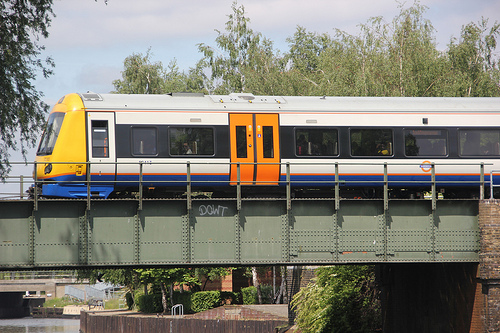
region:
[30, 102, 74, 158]
front windshield of train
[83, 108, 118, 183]
front door of train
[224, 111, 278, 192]
orange double door on train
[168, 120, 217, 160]
passengers window on side of train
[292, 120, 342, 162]
passengers window on side of train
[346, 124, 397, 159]
passengers window on side of train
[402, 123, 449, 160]
passengers window on side of train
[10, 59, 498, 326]
train going across a bridge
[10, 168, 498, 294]
metal bridge for train to cross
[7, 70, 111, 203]
yellow front of train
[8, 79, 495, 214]
a train travels to the right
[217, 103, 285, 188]
door of train is orange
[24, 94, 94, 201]
front of train is yellow and blue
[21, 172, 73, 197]
bumper of train is blue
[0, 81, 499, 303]
train traveling over a bridge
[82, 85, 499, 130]
roof of train is white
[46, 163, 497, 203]
lower part of train is blue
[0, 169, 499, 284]
bridge of train si green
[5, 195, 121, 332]
water below a bridge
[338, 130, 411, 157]
people inside a train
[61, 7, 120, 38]
white clouds in blue sky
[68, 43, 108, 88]
white clouds in blue sky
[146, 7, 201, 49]
white clouds in blue sky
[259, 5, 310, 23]
white clouds in blue sky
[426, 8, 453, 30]
white clouds in blue sky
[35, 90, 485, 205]
passenger train on tracks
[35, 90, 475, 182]
white passenger train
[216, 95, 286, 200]
orange doors of train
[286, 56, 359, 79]
green leaves on brown trees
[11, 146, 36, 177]
white clouds in blue sky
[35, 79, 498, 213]
Yellow and white commuter train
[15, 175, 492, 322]
Green metal bridge under train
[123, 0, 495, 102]
Tall green trees in background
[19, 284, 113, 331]
Canal or river below bridge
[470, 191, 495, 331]
Brick base of train bridge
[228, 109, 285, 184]
Orange doors of train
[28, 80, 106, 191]
Yellow front of the train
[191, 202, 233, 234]
White graffiti on railroad bridge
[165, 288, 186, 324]
Rails on concrete dock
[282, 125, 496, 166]
passenger windows on side of train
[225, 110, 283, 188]
exit doors of the train are orange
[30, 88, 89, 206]
front of the train is yellow and blue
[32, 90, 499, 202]
passenger tain crossing over a bridge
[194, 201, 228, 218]
small amount of graffitti under the train track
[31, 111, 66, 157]
large fron window makes it easier for the engineer to see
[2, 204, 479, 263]
bridge is painted olive green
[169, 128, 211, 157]
large windows allow this passenger a peek outside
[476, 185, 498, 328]
brick supports strengthen the railway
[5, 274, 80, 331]
another bridge can be seen just a short distance away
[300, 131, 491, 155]
passengers can be seen inside the train.